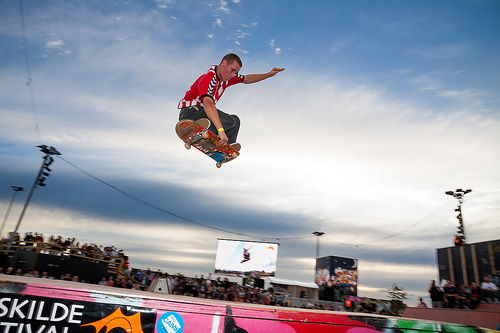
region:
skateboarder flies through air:
[174, 51, 284, 170]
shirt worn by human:
[178, 67, 245, 110]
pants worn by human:
[179, 103, 240, 142]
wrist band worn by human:
[217, 125, 226, 132]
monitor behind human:
[214, 239, 282, 279]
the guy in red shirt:
[147, 25, 324, 202]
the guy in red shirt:
[122, 37, 349, 295]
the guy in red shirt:
[137, 42, 247, 173]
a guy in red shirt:
[95, 23, 320, 196]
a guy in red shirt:
[137, 38, 302, 151]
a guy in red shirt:
[144, 56, 263, 186]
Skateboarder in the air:
[169, 37, 297, 177]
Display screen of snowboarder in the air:
[208, 225, 288, 280]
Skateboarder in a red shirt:
[174, 44, 286, 169]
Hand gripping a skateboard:
[199, 117, 248, 165]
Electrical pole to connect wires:
[9, 134, 61, 248]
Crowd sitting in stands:
[3, 228, 324, 330]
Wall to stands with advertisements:
[0, 273, 478, 331]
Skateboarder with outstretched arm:
[171, 39, 288, 170]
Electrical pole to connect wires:
[443, 179, 485, 256]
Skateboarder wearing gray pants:
[174, 51, 287, 173]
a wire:
[28, 134, 463, 280]